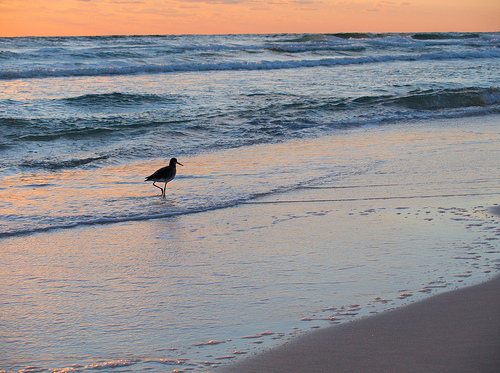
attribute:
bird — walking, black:
[143, 157, 191, 203]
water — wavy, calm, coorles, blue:
[4, 36, 498, 155]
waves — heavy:
[269, 32, 367, 57]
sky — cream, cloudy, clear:
[2, 2, 498, 32]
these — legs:
[161, 185, 170, 200]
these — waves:
[123, 41, 176, 50]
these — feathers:
[171, 165, 175, 168]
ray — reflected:
[252, 12, 286, 30]